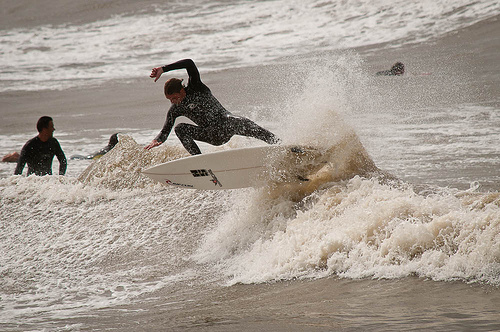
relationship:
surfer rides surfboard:
[141, 59, 285, 156] [140, 145, 305, 190]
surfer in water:
[13, 114, 67, 177] [1, 1, 499, 331]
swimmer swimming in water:
[374, 62, 407, 78] [1, 2, 498, 93]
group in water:
[0, 57, 408, 177] [1, 1, 499, 331]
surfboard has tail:
[140, 145, 305, 190] [289, 144, 330, 184]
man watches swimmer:
[13, 114, 67, 177] [374, 62, 407, 78]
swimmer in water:
[374, 62, 407, 78] [1, 2, 498, 93]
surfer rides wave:
[141, 59, 285, 156] [1, 140, 499, 288]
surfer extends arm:
[141, 59, 285, 156] [144, 107, 177, 155]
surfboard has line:
[140, 145, 305, 190] [141, 164, 267, 177]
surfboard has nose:
[140, 145, 305, 190] [139, 165, 154, 181]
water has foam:
[1, 1, 499, 331] [187, 174, 499, 286]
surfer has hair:
[141, 59, 285, 156] [164, 78, 186, 96]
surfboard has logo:
[140, 145, 305, 190] [192, 168, 212, 178]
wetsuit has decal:
[153, 58, 279, 155] [186, 103, 198, 111]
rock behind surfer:
[0, 151, 21, 165] [13, 114, 67, 177]